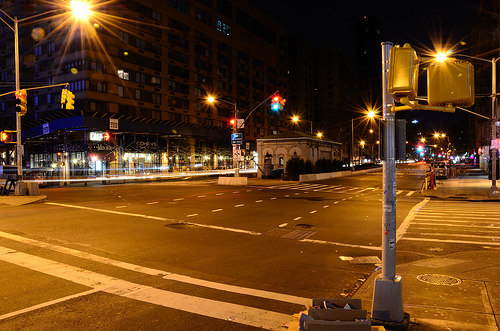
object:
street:
[0, 1, 499, 330]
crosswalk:
[146, 172, 420, 205]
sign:
[0, 132, 13, 142]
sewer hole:
[165, 220, 194, 231]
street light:
[199, 84, 292, 181]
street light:
[3, 0, 112, 197]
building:
[255, 137, 343, 180]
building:
[2, 2, 318, 173]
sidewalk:
[427, 154, 500, 201]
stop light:
[228, 116, 240, 128]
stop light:
[269, 92, 282, 112]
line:
[43, 196, 386, 267]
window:
[119, 67, 138, 82]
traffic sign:
[227, 132, 245, 145]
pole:
[232, 101, 243, 178]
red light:
[270, 94, 283, 103]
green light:
[268, 103, 281, 113]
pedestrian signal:
[65, 89, 74, 108]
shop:
[28, 141, 257, 176]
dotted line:
[117, 181, 276, 210]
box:
[454, 167, 466, 178]